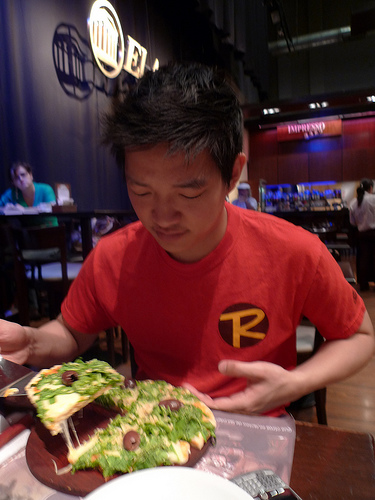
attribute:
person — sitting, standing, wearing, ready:
[56, 54, 285, 440]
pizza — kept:
[13, 333, 260, 486]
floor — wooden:
[334, 395, 364, 417]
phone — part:
[241, 472, 293, 500]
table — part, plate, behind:
[283, 442, 350, 492]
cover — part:
[246, 422, 274, 455]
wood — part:
[283, 457, 315, 497]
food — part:
[38, 359, 97, 424]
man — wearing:
[62, 28, 343, 494]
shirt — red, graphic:
[117, 223, 302, 412]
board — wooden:
[30, 440, 60, 479]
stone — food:
[59, 358, 98, 406]